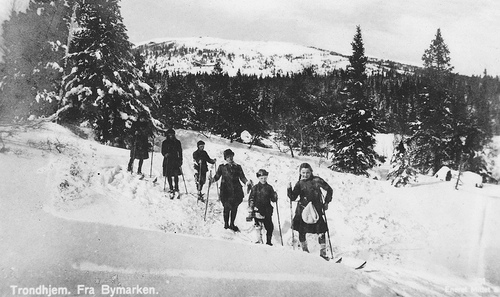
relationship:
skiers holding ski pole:
[116, 96, 336, 251] [316, 200, 344, 263]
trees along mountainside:
[132, 23, 495, 178] [2, 3, 483, 173]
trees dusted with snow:
[31, 9, 481, 166] [421, 202, 477, 241]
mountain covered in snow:
[145, 23, 382, 131] [187, 29, 291, 56]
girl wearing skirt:
[284, 157, 344, 262] [294, 201, 332, 231]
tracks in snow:
[55, 141, 500, 296] [10, 113, 499, 294]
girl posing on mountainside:
[286, 163, 336, 262] [4, 2, 497, 294]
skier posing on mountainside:
[242, 168, 282, 248] [4, 2, 497, 294]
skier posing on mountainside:
[207, 145, 254, 239] [4, 2, 497, 294]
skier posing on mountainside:
[190, 137, 216, 204] [4, 2, 497, 294]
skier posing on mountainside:
[157, 124, 187, 204] [4, 2, 497, 294]